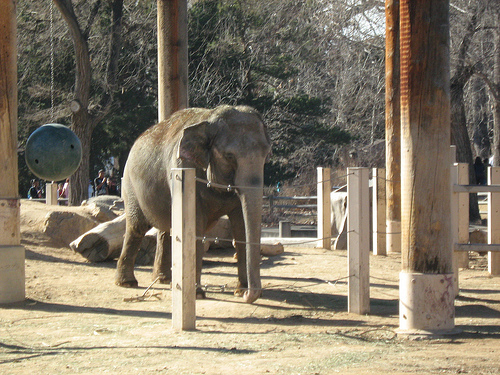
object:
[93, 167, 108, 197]
man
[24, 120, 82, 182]
ball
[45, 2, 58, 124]
chain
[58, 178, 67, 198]
people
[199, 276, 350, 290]
rope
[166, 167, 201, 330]
poles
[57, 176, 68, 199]
woman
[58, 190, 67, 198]
purse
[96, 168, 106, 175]
ballcap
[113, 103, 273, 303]
elephant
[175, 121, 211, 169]
ears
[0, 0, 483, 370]
zoo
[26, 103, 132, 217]
air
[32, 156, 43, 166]
holes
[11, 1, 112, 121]
air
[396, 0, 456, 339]
pole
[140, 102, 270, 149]
patch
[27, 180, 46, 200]
people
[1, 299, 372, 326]
shadow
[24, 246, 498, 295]
shadow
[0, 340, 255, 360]
shadow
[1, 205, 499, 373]
ground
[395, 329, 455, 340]
cemented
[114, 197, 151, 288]
leg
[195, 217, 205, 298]
leg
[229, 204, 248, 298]
leg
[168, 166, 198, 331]
post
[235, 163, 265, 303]
trunk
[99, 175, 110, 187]
camera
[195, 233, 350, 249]
rope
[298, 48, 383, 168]
tree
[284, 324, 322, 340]
straw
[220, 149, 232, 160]
eye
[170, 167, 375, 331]
fence